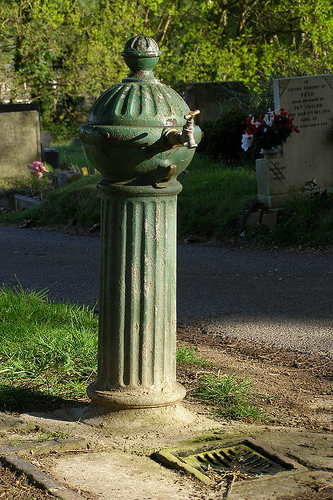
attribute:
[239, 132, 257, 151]
flower — white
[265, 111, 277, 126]
flower — white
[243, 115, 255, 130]
flower — red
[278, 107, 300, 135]
flower — red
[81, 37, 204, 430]
monument — green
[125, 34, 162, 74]
structure — round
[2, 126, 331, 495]
ground — gray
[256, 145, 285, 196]
vase — stone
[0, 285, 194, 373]
grass — green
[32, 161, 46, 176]
flower — pink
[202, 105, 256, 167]
bush — green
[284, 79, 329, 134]
epitaph — gray